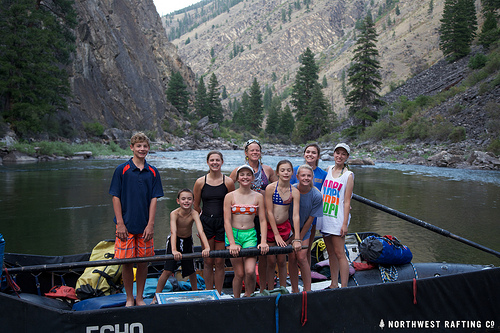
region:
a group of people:
[28, 81, 484, 321]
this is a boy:
[103, 113, 190, 303]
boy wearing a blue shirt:
[97, 147, 169, 244]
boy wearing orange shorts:
[103, 210, 167, 262]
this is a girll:
[265, 146, 300, 302]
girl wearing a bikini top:
[243, 164, 300, 215]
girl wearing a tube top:
[228, 194, 265, 225]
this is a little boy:
[159, 176, 213, 284]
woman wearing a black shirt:
[183, 165, 235, 241]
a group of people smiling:
[111, 119, 387, 293]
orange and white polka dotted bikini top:
[228, 203, 262, 218]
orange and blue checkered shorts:
[113, 230, 155, 260]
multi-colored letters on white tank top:
[318, 173, 344, 222]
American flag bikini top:
[269, 176, 297, 208]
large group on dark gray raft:
[0, 130, 499, 332]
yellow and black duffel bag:
[71, 236, 131, 300]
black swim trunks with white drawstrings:
[157, 228, 199, 279]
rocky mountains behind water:
[1, 0, 499, 177]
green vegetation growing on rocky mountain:
[1, 0, 93, 142]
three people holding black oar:
[154, 160, 305, 315]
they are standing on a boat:
[11, 123, 498, 325]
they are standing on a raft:
[7, 124, 497, 329]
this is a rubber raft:
[2, 253, 495, 332]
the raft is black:
[2, 246, 497, 331]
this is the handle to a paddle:
[5, 235, 305, 280]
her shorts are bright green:
[222, 227, 262, 254]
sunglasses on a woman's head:
[236, 129, 266, 146]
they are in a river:
[3, 123, 498, 331]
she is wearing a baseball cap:
[325, 133, 360, 282]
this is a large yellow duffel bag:
[82, 229, 139, 301]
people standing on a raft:
[101, 133, 394, 303]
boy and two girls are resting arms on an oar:
[167, 160, 300, 296]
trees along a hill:
[155, 0, 495, 140]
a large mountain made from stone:
[2, 2, 215, 138]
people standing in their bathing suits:
[112, 130, 377, 295]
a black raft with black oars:
[1, 190, 492, 325]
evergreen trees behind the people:
[170, 15, 380, 147]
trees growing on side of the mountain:
[435, 1, 496, 72]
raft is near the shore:
[15, 96, 498, 328]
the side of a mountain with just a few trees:
[158, 2, 470, 101]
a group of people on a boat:
[73, 113, 369, 310]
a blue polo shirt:
[97, 155, 167, 234]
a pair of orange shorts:
[102, 207, 164, 264]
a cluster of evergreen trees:
[156, 32, 397, 140]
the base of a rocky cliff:
[26, 1, 201, 136]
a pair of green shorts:
[226, 230, 256, 247]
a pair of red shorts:
[266, 217, 303, 249]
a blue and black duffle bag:
[352, 232, 429, 272]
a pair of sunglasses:
[244, 135, 261, 150]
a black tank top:
[192, 177, 232, 221]